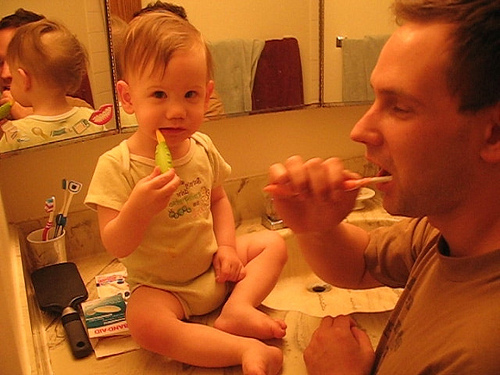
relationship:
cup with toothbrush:
[26, 224, 71, 268] [43, 196, 57, 241]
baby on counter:
[84, 11, 290, 374] [33, 185, 414, 373]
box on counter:
[78, 292, 141, 359] [33, 185, 414, 373]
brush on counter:
[29, 261, 94, 361] [33, 185, 414, 373]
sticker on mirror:
[90, 101, 114, 127] [2, 1, 399, 151]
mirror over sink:
[2, 1, 399, 151] [261, 221, 403, 318]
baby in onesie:
[84, 11, 290, 374] [84, 131, 235, 321]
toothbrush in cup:
[43, 196, 57, 241] [26, 224, 71, 268]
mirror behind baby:
[2, 1, 399, 151] [84, 11, 290, 374]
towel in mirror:
[252, 36, 306, 119] [2, 1, 399, 151]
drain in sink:
[307, 282, 329, 294] [261, 221, 403, 318]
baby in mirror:
[84, 11, 290, 374] [2, 1, 399, 151]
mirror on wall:
[2, 1, 399, 151] [1, 102, 377, 227]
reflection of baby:
[0, 17, 107, 155] [84, 11, 290, 374]